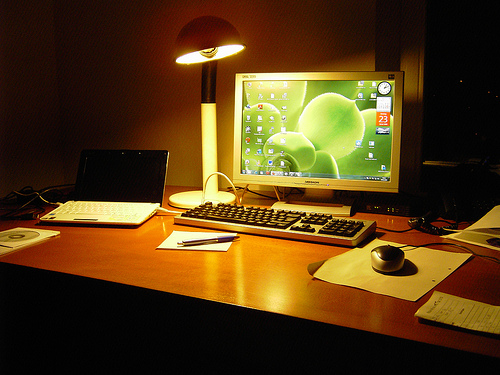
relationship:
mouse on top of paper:
[372, 245, 403, 268] [308, 234, 472, 300]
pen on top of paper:
[179, 240, 239, 247] [162, 230, 233, 256]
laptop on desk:
[47, 150, 174, 226] [3, 190, 499, 348]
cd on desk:
[3, 227, 47, 244] [3, 190, 499, 348]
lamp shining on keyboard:
[181, 22, 234, 205] [190, 202, 378, 241]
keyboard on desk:
[190, 202, 378, 241] [3, 190, 499, 348]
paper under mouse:
[308, 234, 472, 300] [372, 245, 403, 268]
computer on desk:
[241, 81, 393, 180] [3, 190, 499, 348]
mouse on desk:
[372, 245, 403, 268] [3, 190, 499, 348]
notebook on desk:
[162, 230, 233, 256] [3, 190, 499, 348]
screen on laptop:
[82, 154, 158, 195] [47, 150, 174, 226]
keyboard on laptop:
[52, 203, 149, 229] [47, 150, 174, 226]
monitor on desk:
[241, 81, 393, 180] [3, 190, 499, 348]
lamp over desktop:
[181, 22, 234, 205] [241, 81, 393, 180]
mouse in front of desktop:
[372, 245, 403, 268] [241, 81, 393, 180]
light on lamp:
[181, 47, 241, 64] [181, 22, 234, 205]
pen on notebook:
[179, 240, 239, 247] [162, 230, 233, 256]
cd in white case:
[3, 227, 47, 244] [6, 227, 63, 255]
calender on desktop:
[376, 95, 395, 133] [241, 81, 393, 180]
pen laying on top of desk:
[179, 240, 239, 247] [3, 190, 499, 348]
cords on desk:
[10, 186, 58, 216] [3, 190, 499, 348]